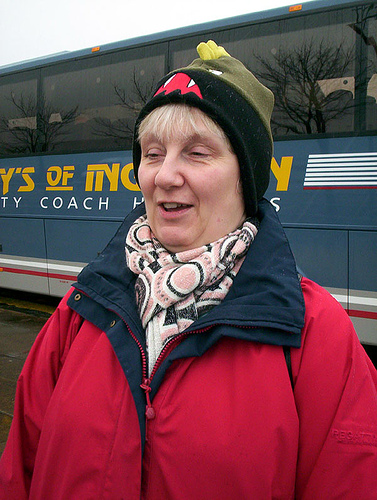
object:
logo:
[332, 428, 376, 445]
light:
[92, 46, 100, 51]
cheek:
[194, 167, 221, 196]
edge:
[71, 281, 148, 391]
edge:
[279, 347, 303, 498]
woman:
[0, 38, 377, 500]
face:
[137, 105, 240, 247]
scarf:
[123, 214, 258, 377]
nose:
[154, 161, 184, 191]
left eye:
[186, 146, 212, 160]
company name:
[1, 155, 293, 194]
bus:
[0, 0, 377, 345]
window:
[168, 5, 359, 137]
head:
[132, 40, 276, 252]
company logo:
[0, 157, 294, 215]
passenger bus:
[0, 0, 377, 345]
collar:
[65, 195, 307, 394]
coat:
[0, 196, 377, 500]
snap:
[74, 294, 80, 301]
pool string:
[140, 383, 155, 420]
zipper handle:
[140, 384, 156, 419]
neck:
[134, 248, 229, 299]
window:
[40, 40, 168, 153]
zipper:
[75, 288, 259, 390]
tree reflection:
[244, 35, 375, 139]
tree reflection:
[90, 64, 156, 147]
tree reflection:
[0, 90, 82, 156]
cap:
[132, 38, 275, 215]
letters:
[0, 168, 15, 195]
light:
[289, 5, 302, 11]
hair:
[138, 104, 225, 143]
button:
[109, 320, 115, 328]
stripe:
[1, 261, 376, 323]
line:
[0, 298, 54, 316]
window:
[362, 5, 377, 136]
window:
[0, 72, 37, 154]